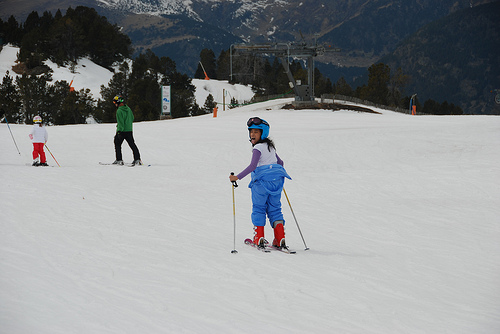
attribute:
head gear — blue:
[246, 115, 276, 145]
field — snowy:
[37, 116, 492, 315]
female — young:
[234, 111, 291, 257]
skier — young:
[226, 107, 318, 251]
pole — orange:
[211, 104, 217, 117]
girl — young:
[210, 94, 310, 279]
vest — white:
[256, 132, 280, 177]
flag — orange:
[66, 77, 75, 94]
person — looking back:
[227, 117, 289, 248]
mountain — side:
[4, 7, 482, 75]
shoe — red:
[271, 216, 289, 248]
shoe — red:
[250, 223, 265, 246]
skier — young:
[229, 114, 293, 254]